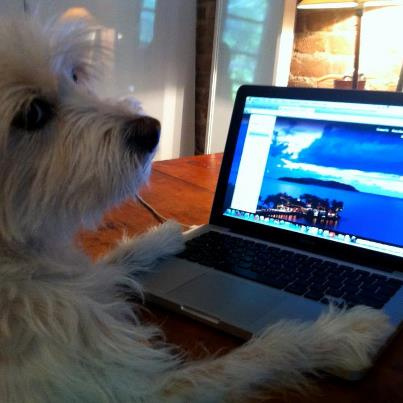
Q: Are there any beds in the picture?
A: No, there are no beds.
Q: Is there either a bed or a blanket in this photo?
A: No, there are no beds or blankets.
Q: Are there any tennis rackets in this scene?
A: No, there are no tennis rackets.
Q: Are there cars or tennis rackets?
A: No, there are no tennis rackets or cars.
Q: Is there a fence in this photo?
A: No, there are no fences.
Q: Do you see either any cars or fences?
A: No, there are no fences or cars.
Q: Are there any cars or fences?
A: No, there are no fences or cars.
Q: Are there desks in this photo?
A: Yes, there is a desk.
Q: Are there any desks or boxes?
A: Yes, there is a desk.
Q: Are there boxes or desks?
A: Yes, there is a desk.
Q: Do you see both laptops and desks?
A: Yes, there are both a desk and a laptop.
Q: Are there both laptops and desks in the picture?
A: Yes, there are both a desk and a laptop.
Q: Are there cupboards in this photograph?
A: No, there are no cupboards.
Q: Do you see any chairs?
A: No, there are no chairs.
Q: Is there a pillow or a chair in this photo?
A: No, there are no chairs or pillows.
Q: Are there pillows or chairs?
A: No, there are no chairs or pillows.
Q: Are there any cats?
A: No, there are no cats.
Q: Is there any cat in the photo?
A: No, there are no cats.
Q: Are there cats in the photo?
A: No, there are no cats.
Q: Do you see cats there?
A: No, there are no cats.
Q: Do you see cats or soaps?
A: No, there are no cats or soaps.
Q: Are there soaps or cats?
A: No, there are no cats or soaps.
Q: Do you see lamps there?
A: Yes, there is a lamp.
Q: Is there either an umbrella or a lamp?
A: Yes, there is a lamp.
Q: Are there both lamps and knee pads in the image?
A: No, there is a lamp but no knee pads.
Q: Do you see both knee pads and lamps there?
A: No, there is a lamp but no knee pads.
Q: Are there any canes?
A: No, there are no canes.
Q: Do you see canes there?
A: No, there are no canes.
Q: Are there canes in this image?
A: No, there are no canes.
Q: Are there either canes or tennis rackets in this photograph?
A: No, there are no canes or tennis rackets.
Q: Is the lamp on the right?
A: Yes, the lamp is on the right of the image.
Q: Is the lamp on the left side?
A: No, the lamp is on the right of the image.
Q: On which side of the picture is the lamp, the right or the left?
A: The lamp is on the right of the image.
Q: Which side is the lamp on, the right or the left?
A: The lamp is on the right of the image.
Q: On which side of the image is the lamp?
A: The lamp is on the right of the image.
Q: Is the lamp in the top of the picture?
A: Yes, the lamp is in the top of the image.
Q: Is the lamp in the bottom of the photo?
A: No, the lamp is in the top of the image.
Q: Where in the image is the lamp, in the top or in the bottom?
A: The lamp is in the top of the image.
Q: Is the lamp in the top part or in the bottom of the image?
A: The lamp is in the top of the image.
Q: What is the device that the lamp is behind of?
A: The device is a laptop.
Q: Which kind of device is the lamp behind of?
A: The lamp is behind the laptop.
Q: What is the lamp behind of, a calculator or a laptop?
A: The lamp is behind a laptop.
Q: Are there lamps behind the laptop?
A: Yes, there is a lamp behind the laptop.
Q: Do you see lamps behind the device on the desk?
A: Yes, there is a lamp behind the laptop.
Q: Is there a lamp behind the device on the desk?
A: Yes, there is a lamp behind the laptop.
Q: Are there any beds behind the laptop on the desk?
A: No, there is a lamp behind the laptop computer.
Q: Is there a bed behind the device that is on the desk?
A: No, there is a lamp behind the laptop computer.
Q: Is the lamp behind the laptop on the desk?
A: Yes, the lamp is behind the laptop computer.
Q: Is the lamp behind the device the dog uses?
A: Yes, the lamp is behind the laptop computer.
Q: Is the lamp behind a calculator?
A: No, the lamp is behind the laptop computer.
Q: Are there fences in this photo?
A: No, there are no fences.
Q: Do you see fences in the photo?
A: No, there are no fences.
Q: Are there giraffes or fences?
A: No, there are no fences or giraffes.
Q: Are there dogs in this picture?
A: Yes, there is a dog.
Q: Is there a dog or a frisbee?
A: Yes, there is a dog.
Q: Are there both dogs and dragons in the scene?
A: No, there is a dog but no dragons.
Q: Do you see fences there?
A: No, there are no fences.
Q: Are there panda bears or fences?
A: No, there are no fences or panda bears.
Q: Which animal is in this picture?
A: The animal is a dog.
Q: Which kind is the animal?
A: The animal is a dog.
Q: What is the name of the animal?
A: The animal is a dog.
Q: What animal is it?
A: The animal is a dog.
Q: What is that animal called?
A: This is a dog.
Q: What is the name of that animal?
A: This is a dog.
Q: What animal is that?
A: This is a dog.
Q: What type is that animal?
A: This is a dog.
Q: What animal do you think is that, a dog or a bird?
A: This is a dog.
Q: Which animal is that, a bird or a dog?
A: This is a dog.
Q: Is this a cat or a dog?
A: This is a dog.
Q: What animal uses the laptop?
A: The dog uses the laptop.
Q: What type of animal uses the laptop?
A: The animal is a dog.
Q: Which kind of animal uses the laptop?
A: The animal is a dog.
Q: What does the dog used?
A: The dog uses a laptop.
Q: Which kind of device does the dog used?
A: The dog uses a laptop computer.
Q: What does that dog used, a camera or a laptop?
A: The dog uses a laptop.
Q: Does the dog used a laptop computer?
A: Yes, the dog uses a laptop computer.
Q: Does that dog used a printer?
A: No, the dog uses a laptop computer.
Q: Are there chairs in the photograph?
A: No, there are no chairs.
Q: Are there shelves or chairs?
A: No, there are no chairs or shelves.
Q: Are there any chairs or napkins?
A: No, there are no napkins or chairs.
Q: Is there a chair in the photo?
A: No, there are no chairs.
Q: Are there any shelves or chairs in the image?
A: No, there are no chairs or shelves.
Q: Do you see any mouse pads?
A: Yes, there is a mouse pad.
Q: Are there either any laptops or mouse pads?
A: Yes, there is a mouse pad.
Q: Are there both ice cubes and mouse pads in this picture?
A: No, there is a mouse pad but no ice cubes.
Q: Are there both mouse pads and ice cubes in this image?
A: No, there is a mouse pad but no ice cubes.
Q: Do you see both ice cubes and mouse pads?
A: No, there is a mouse pad but no ice cubes.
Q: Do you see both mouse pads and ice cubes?
A: No, there is a mouse pad but no ice cubes.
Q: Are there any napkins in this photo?
A: No, there are no napkins.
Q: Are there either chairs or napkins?
A: No, there are no napkins or chairs.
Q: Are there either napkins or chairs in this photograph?
A: No, there are no napkins or chairs.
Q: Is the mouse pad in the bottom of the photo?
A: Yes, the mouse pad is in the bottom of the image.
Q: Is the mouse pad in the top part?
A: No, the mouse pad is in the bottom of the image.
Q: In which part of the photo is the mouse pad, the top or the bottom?
A: The mouse pad is in the bottom of the image.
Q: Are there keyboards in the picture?
A: Yes, there is a keyboard.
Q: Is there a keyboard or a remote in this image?
A: Yes, there is a keyboard.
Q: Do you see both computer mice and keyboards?
A: No, there is a keyboard but no computer mice.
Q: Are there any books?
A: No, there are no books.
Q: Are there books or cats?
A: No, there are no books or cats.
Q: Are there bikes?
A: No, there are no bikes.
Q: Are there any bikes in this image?
A: No, there are no bikes.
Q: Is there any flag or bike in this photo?
A: No, there are no bikes or flags.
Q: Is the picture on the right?
A: Yes, the picture is on the right of the image.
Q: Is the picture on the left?
A: No, the picture is on the right of the image.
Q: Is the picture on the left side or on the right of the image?
A: The picture is on the right of the image.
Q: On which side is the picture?
A: The picture is on the right of the image.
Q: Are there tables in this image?
A: Yes, there is a table.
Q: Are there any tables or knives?
A: Yes, there is a table.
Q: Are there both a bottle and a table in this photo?
A: No, there is a table but no bottles.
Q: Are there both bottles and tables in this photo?
A: No, there is a table but no bottles.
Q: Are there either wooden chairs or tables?
A: Yes, there is a wood table.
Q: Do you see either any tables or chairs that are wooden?
A: Yes, the table is wooden.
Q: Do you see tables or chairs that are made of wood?
A: Yes, the table is made of wood.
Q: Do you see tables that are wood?
A: Yes, there is a wood table.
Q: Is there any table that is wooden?
A: Yes, there is a table that is wooden.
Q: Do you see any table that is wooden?
A: Yes, there is a table that is wooden.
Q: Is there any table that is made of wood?
A: Yes, there is a table that is made of wood.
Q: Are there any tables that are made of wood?
A: Yes, there is a table that is made of wood.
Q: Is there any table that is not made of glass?
A: Yes, there is a table that is made of wood.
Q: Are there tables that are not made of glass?
A: Yes, there is a table that is made of wood.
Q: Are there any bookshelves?
A: No, there are no bookshelves.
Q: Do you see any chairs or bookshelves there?
A: No, there are no bookshelves or chairs.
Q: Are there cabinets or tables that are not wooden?
A: No, there is a table but it is wooden.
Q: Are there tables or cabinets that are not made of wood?
A: No, there is a table but it is made of wood.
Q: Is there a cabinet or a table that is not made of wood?
A: No, there is a table but it is made of wood.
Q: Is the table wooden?
A: Yes, the table is wooden.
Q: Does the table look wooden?
A: Yes, the table is wooden.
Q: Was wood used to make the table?
A: Yes, the table is made of wood.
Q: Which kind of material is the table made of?
A: The table is made of wood.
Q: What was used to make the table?
A: The table is made of wood.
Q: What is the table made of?
A: The table is made of wood.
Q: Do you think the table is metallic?
A: No, the table is wooden.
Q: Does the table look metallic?
A: No, the table is wooden.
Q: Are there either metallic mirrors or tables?
A: No, there is a table but it is wooden.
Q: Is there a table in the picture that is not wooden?
A: No, there is a table but it is wooden.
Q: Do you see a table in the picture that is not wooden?
A: No, there is a table but it is wooden.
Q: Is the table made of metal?
A: No, the table is made of wood.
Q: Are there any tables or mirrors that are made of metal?
A: No, there is a table but it is made of wood.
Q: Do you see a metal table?
A: No, there is a table but it is made of wood.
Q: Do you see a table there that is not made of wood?
A: No, there is a table but it is made of wood.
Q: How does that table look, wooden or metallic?
A: The table is wooden.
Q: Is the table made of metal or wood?
A: The table is made of wood.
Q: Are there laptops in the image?
A: Yes, there is a laptop.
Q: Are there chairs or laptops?
A: Yes, there is a laptop.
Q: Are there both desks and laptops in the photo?
A: Yes, there are both a laptop and a desk.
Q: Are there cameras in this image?
A: No, there are no cameras.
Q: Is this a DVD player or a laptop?
A: This is a laptop.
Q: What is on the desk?
A: The laptop computer is on the desk.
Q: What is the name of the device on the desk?
A: The device is a laptop.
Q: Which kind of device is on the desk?
A: The device is a laptop.